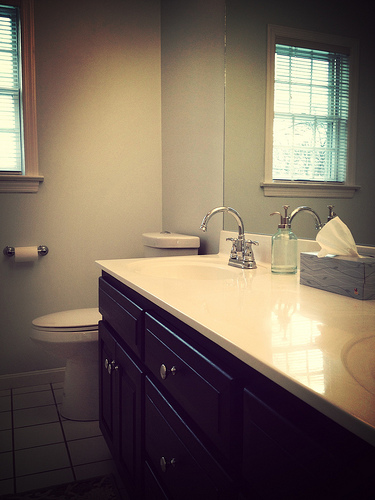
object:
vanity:
[95, 228, 375, 500]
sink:
[122, 257, 237, 284]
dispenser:
[269, 204, 298, 274]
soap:
[271, 239, 297, 274]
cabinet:
[97, 260, 375, 500]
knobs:
[159, 455, 180, 475]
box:
[298, 250, 375, 302]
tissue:
[314, 215, 361, 260]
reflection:
[257, 19, 360, 199]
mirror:
[219, 3, 375, 253]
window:
[258, 20, 359, 198]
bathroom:
[0, 0, 374, 498]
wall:
[0, 0, 162, 384]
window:
[0, 0, 44, 195]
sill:
[0, 174, 45, 195]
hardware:
[108, 364, 119, 376]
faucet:
[199, 206, 259, 270]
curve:
[200, 204, 245, 240]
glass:
[271, 228, 298, 274]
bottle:
[268, 221, 298, 276]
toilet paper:
[13, 246, 39, 264]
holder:
[3, 245, 49, 258]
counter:
[92, 230, 375, 446]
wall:
[161, 0, 375, 258]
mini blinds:
[0, 7, 26, 175]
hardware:
[158, 362, 177, 380]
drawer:
[142, 310, 236, 467]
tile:
[11, 403, 61, 429]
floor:
[0, 380, 129, 500]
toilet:
[29, 230, 201, 424]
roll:
[14, 245, 39, 264]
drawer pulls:
[143, 374, 239, 499]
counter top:
[94, 252, 375, 432]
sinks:
[339, 322, 375, 399]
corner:
[156, 0, 168, 234]